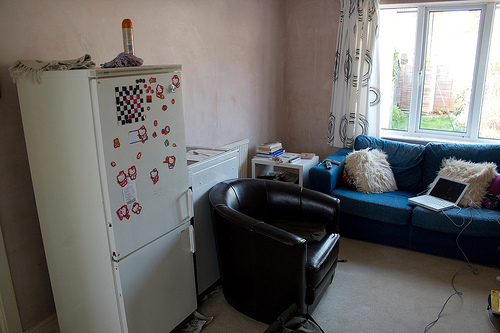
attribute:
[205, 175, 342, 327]
chair — black, dark, leather, brown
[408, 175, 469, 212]
laptop — white, open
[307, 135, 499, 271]
couch — blue, sagging, under window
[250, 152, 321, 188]
table — white, small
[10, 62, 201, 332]
refrigerator — white, covered in magnets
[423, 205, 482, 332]
cord — running across floor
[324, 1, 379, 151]
curtain — black, white, white with design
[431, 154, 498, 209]
pillow — shaggy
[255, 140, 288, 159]
books — stacked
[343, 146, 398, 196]
pillow — shaggy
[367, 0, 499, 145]
window — three paned, closed